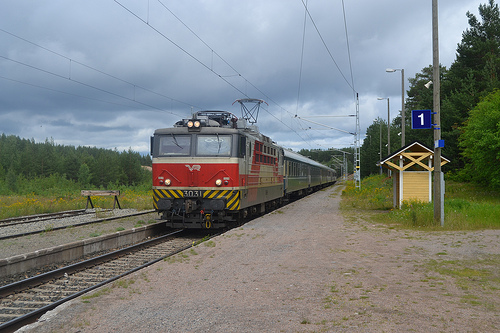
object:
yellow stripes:
[177, 189, 184, 197]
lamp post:
[401, 68, 406, 147]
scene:
[1, 0, 499, 331]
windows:
[196, 134, 234, 157]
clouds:
[0, 0, 499, 144]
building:
[375, 142, 450, 210]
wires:
[340, 0, 355, 90]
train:
[146, 106, 339, 233]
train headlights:
[194, 120, 201, 127]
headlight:
[215, 179, 222, 187]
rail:
[77, 190, 120, 196]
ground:
[1, 176, 499, 330]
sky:
[0, 0, 500, 156]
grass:
[338, 170, 500, 232]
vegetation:
[0, 131, 144, 195]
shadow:
[148, 221, 210, 240]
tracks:
[1, 230, 230, 331]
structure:
[377, 141, 452, 211]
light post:
[431, 0, 445, 226]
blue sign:
[410, 109, 433, 130]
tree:
[459, 86, 499, 196]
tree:
[363, 116, 388, 178]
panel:
[153, 187, 241, 230]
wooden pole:
[397, 170, 432, 208]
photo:
[0, 1, 498, 333]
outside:
[0, 0, 500, 333]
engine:
[150, 125, 285, 230]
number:
[199, 191, 202, 197]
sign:
[410, 109, 435, 129]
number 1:
[417, 112, 426, 125]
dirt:
[0, 185, 499, 330]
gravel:
[253, 287, 259, 291]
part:
[0, 178, 167, 249]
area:
[0, 134, 156, 197]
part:
[313, 251, 499, 332]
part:
[275, 206, 434, 231]